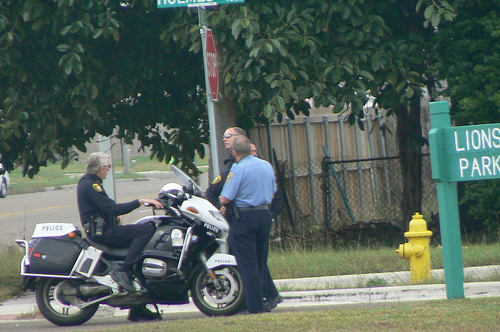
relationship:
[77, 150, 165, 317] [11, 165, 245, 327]
cop riding h bike